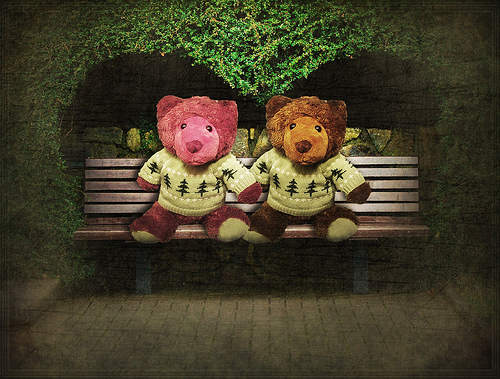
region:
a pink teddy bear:
[132, 61, 260, 251]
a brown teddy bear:
[255, 63, 366, 248]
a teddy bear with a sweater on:
[140, 48, 281, 265]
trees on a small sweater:
[122, 95, 272, 265]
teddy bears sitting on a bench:
[78, 79, 485, 257]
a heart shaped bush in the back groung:
[31, 8, 475, 209]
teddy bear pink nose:
[175, 135, 206, 167]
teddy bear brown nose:
[278, 135, 330, 167]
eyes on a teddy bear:
[165, 101, 229, 145]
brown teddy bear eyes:
[277, 109, 348, 140]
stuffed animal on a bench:
[237, 86, 373, 256]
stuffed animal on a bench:
[124, 87, 262, 256]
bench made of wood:
[62, 153, 438, 305]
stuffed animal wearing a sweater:
[114, 90, 268, 256]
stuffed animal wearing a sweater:
[228, 91, 374, 256]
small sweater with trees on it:
[139, 142, 255, 214]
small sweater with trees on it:
[240, 146, 374, 222]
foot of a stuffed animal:
[198, 198, 254, 244]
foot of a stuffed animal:
[120, 194, 180, 251]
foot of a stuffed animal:
[242, 198, 293, 250]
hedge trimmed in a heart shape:
[6, 3, 491, 273]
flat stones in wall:
[83, 123, 435, 160]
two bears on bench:
[71, 91, 432, 295]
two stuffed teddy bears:
[130, 91, 372, 246]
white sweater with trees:
[142, 151, 257, 213]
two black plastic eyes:
[288, 119, 322, 133]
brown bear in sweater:
[246, 96, 368, 243]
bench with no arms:
[79, 154, 429, 295]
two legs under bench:
[135, 242, 372, 293]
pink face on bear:
[176, 118, 216, 165]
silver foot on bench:
[116, 250, 167, 309]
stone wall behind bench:
[388, 255, 439, 304]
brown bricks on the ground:
[196, 303, 293, 343]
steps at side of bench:
[7, 275, 79, 321]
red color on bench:
[97, 181, 124, 223]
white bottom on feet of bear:
[212, 216, 247, 244]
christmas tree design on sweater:
[157, 163, 234, 197]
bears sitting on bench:
[117, 81, 359, 240]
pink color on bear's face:
[160, 89, 247, 166]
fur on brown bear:
[286, 92, 327, 109]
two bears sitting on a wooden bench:
[64, 49, 444, 276]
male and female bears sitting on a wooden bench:
[126, 85, 378, 243]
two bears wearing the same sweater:
[142, 161, 344, 213]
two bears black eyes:
[174, 118, 326, 135]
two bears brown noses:
[182, 140, 320, 157]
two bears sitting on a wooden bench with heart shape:
[64, 43, 411, 327]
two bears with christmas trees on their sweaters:
[159, 168, 323, 204]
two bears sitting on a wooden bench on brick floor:
[42, 63, 426, 339]